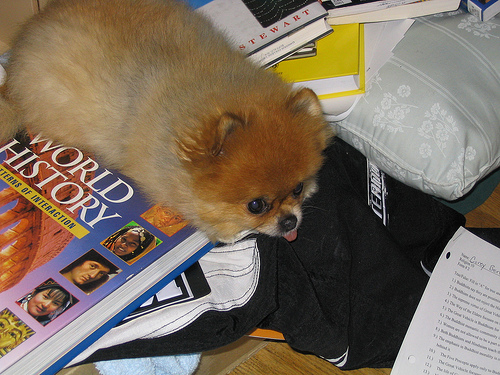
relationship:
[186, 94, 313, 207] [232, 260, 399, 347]
dog on clothes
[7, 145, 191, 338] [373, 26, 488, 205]
book on pillow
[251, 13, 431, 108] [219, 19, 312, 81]
bunch of books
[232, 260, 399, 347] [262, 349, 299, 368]
clothes on floor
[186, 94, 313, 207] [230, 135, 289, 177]
dog with orange fur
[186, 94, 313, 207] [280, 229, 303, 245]
dog with tongue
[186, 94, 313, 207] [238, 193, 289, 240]
dog with eye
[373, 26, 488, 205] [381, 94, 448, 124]
pillow with flowers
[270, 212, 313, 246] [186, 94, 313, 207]
nose of dog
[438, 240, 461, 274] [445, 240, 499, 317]
paper with hole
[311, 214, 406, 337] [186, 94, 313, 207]
shorts under dog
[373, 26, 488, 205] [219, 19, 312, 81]
pillow under books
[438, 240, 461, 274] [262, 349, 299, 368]
paper on floor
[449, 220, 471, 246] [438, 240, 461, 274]
staple in paper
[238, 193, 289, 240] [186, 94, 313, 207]
eye of dog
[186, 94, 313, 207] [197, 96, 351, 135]
dog with ears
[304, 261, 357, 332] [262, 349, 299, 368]
sweatshirt on floor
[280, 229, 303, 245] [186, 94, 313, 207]
tongue of dog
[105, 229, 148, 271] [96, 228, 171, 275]
head of woman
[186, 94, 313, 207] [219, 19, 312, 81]
dog on books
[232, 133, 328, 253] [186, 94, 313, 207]
face of dog